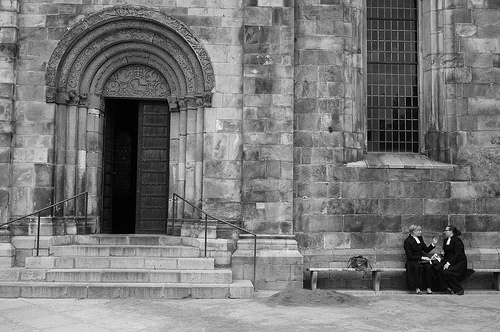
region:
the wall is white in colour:
[249, 148, 276, 217]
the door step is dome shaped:
[21, 9, 210, 242]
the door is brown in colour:
[106, 102, 165, 248]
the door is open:
[103, 102, 134, 224]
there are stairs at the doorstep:
[70, 203, 217, 321]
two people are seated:
[381, 200, 472, 296]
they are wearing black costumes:
[401, 195, 479, 300]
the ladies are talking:
[396, 218, 473, 293]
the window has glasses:
[356, 0, 428, 155]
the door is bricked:
[218, 125, 321, 205]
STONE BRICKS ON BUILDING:
[227, 84, 330, 191]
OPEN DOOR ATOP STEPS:
[107, 63, 167, 230]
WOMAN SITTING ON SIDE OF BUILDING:
[391, 209, 430, 296]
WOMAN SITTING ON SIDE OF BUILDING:
[436, 225, 477, 273]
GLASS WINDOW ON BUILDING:
[361, 16, 419, 155]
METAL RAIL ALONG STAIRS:
[157, 174, 264, 274]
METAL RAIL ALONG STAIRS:
[18, 174, 90, 239]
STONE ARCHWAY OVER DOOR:
[67, 30, 211, 137]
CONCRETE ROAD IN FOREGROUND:
[137, 306, 234, 325]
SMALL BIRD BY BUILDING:
[348, 241, 380, 271]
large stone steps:
[3, 216, 281, 304]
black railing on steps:
[170, 186, 269, 276]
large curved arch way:
[43, 10, 232, 116]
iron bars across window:
[362, 12, 449, 167]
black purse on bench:
[343, 249, 384, 273]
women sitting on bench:
[391, 210, 485, 285]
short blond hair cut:
[399, 218, 423, 231]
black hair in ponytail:
[445, 220, 472, 237]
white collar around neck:
[412, 235, 431, 242]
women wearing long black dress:
[401, 219, 481, 286]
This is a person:
[431, 221, 473, 298]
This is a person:
[401, 212, 436, 297]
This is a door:
[93, 58, 173, 230]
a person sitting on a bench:
[398, 217, 437, 296]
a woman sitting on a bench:
[435, 217, 477, 293]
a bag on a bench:
[342, 244, 372, 279]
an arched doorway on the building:
[42, 8, 216, 235]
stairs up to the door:
[3, 222, 256, 299]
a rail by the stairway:
[167, 190, 264, 283]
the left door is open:
[92, 97, 136, 230]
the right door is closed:
[136, 101, 170, 232]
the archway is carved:
[45, 8, 217, 110]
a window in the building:
[341, 0, 463, 178]